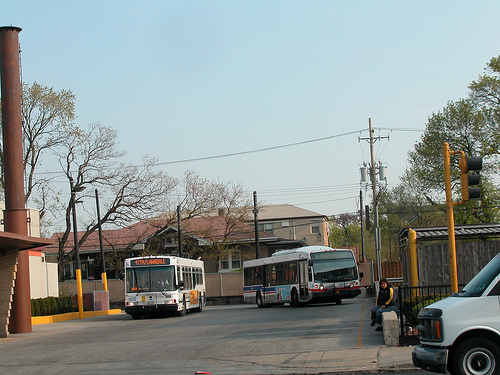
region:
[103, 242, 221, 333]
White bus on the left side of the road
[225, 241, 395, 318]
White bus on the right side of the road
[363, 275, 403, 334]
Woman sitting on the concrete barrier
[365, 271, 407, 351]
Concrete barrier on the side of the road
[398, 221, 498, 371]
White vehicle on the side street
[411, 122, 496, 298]
Orange street light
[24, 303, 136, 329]
Curb painted orange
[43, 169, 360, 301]
Structures behind the buses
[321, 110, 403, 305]
Telephone pole to the right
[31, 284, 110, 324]
Small bushes next to the building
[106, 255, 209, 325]
bus parked on street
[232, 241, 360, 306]
bus parked on street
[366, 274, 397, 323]
person sitting on ledge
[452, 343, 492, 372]
rubber tire on van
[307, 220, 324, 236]
window on brick building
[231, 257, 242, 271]
window on brick building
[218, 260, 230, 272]
window on brick building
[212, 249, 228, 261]
window on brick building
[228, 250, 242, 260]
window on brick building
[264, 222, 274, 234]
window on brick building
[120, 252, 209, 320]
a white public service bus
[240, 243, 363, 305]
a white public service bus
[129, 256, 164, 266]
electronic bus destination sign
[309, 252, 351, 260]
electronic bus destination sign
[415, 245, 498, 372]
a large white van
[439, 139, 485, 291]
a three way stop sign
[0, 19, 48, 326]
a large brown stack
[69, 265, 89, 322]
a tall yellow pole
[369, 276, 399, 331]
man sitting on a curb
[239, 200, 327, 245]
light brown building in distance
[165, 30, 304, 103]
The sky is blue.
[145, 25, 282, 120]
The sky is clear.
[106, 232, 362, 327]
Two buses.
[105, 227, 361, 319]
The buses are white.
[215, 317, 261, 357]
The asphalt is gray.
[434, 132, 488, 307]
A traffic light.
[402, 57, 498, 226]
The trees are green.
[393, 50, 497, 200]
Trees are in the background.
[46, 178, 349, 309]
Buildings are in the background.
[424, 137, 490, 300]
The light pole is yellow.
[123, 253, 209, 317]
white bus on a street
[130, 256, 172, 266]
digital orange text on the front of a bus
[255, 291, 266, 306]
back bus wheel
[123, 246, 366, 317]
two buses on a street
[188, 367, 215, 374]
red object in the middle of the street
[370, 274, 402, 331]
woman in a black shirt sitting down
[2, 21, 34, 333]
tall brown pole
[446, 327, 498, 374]
black wheel on a white vehicle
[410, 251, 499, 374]
white vehicle on the street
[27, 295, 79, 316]
bushes